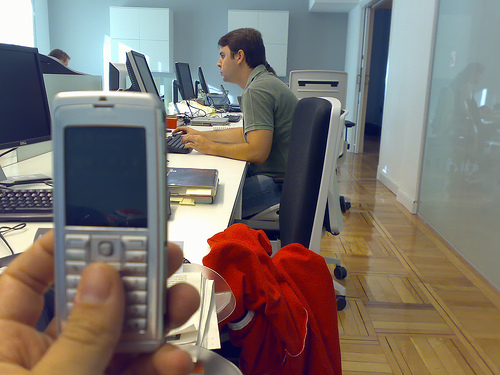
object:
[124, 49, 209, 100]
flatscreen monitors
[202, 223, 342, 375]
jacket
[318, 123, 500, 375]
floor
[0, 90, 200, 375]
person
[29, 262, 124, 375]
thumb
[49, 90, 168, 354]
cellphone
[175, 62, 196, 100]
screen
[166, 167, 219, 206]
books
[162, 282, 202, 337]
finger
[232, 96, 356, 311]
chairs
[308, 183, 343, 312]
rollers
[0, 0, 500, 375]
office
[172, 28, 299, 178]
man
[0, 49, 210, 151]
monitors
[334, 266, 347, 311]
wheels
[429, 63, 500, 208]
reflection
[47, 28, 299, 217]
people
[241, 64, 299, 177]
polo shirt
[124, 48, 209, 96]
three monitors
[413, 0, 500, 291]
glass divider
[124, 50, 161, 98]
computer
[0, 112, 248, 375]
desks